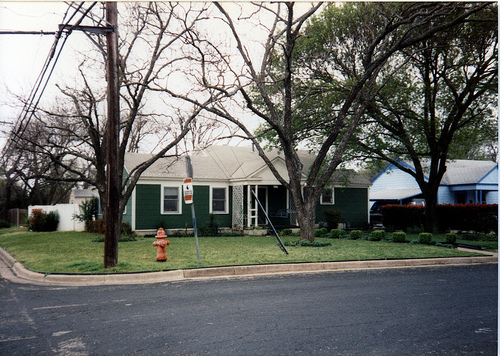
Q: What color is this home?
A: Green.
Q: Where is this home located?
A: On the corner.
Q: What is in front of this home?
A: Trees.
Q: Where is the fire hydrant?
A: On the lawn.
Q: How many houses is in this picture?
A: Two.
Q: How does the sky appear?
A: Clear.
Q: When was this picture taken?
A: Day time.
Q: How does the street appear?
A: Empty.